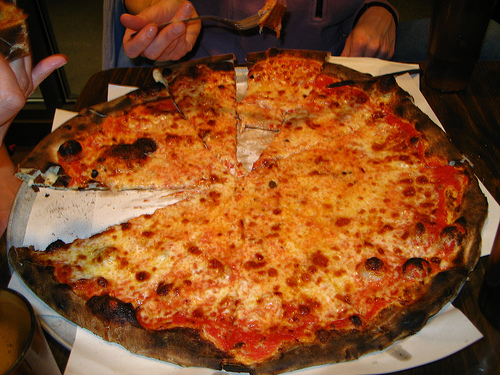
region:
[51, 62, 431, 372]
a whole cheese pizza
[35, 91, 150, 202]
a burnt slice of pizza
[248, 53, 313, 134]
a bitten piece of pizza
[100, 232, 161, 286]
a lot of pizza cheese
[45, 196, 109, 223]
a small grease stain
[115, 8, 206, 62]
the hand of a person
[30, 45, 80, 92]
the thumb of a person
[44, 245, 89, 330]
the crust of a pizza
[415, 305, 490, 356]
a piece of white cardboad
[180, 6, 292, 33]
a small silver fork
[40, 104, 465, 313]
large pizza kept over paper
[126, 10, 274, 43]
man holding fork in hand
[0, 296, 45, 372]
glass kept on table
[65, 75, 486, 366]
pizza kept on table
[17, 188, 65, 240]
white color plate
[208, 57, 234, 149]
triangle slice of pizza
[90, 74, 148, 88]
brown wooden table top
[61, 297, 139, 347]
brown color deep baked edge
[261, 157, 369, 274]
orange and yellow color topping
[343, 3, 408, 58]
left hand of the man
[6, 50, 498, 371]
pizza on a pan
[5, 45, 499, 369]
pizza cut into triangles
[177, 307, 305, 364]
red sauce sticking out of the cheese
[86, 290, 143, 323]
black spot on the crust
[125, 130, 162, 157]
dark spot on the cheese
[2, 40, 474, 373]
cheese pizza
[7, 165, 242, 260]
a slice is missing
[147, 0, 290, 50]
fork with food on it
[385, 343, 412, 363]
grease stain on the paper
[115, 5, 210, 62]
fingers on the handle of the fork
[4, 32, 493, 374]
A pizza in the foreground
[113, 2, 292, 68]
Person is holding a fork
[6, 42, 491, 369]
The pizza crust is dark brown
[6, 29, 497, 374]
The pizza is a cheese pizza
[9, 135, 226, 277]
Pizza slice is missing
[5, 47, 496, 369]
Pizza is on a wooden table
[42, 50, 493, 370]
The table is dark brown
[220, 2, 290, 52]
Pizza is on the fork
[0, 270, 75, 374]
A cup in the foreground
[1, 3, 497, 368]
Photo was taken indoors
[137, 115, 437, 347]
pizza on the plate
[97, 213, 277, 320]
cheese on the pizza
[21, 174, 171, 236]
the slice is missing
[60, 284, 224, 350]
the crust is burnt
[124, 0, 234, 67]
fork in the hand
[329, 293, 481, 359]
paper under the pizza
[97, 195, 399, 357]
pizza cut into slices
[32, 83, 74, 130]
side of the table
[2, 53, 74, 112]
hand on the left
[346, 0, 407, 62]
hand on the right